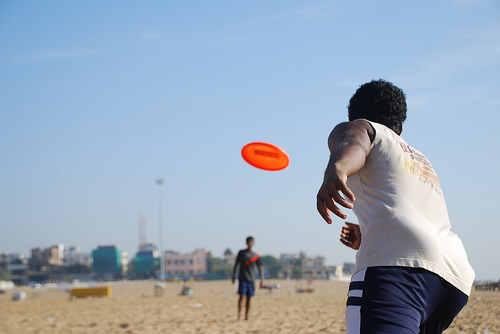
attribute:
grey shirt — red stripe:
[227, 247, 266, 280]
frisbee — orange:
[228, 137, 348, 207]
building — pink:
[93, 245, 120, 277]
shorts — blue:
[230, 273, 258, 299]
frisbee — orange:
[213, 127, 297, 180]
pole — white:
[157, 171, 164, 283]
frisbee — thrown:
[223, 124, 318, 186]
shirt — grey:
[233, 246, 263, 281]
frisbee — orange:
[240, 139, 290, 174]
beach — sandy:
[1, 278, 499, 332]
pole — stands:
[147, 172, 178, 311]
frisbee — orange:
[228, 121, 307, 181]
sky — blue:
[0, 0, 499, 282]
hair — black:
[343, 76, 409, 128]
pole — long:
[152, 176, 167, 283]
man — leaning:
[322, 78, 467, 332]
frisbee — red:
[239, 139, 292, 171]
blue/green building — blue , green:
[128, 242, 165, 278]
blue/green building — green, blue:
[85, 238, 124, 282]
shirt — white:
[348, 119, 476, 296]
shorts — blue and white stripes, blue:
[344, 264, 469, 332]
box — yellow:
[59, 277, 126, 302]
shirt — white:
[297, 92, 499, 261]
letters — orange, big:
[393, 142, 440, 191]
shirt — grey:
[219, 223, 272, 288]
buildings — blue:
[92, 232, 181, 288]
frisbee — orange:
[227, 98, 309, 176]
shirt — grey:
[224, 247, 284, 293]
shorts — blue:
[228, 267, 279, 294]